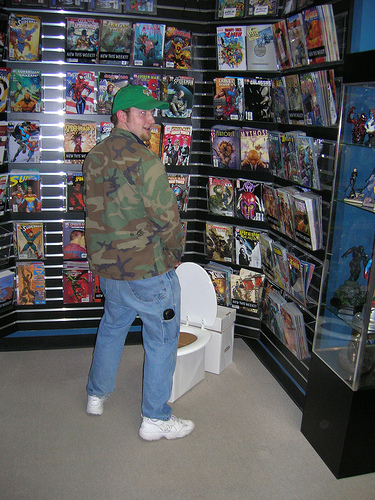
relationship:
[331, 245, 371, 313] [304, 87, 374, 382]
figurine behind glass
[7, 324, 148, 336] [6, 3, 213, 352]
line on wall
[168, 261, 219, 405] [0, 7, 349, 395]
toilet near shelving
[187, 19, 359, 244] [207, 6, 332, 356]
comic books on shelves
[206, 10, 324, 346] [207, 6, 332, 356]
magazines on shelves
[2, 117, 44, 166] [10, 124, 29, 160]
comic featuring batman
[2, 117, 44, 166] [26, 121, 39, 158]
comic featuring superman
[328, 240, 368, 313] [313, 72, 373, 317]
figurine inside glass case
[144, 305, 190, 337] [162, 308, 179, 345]
case inside case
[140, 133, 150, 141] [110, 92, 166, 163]
beard on man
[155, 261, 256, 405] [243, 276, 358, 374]
toilet in corner of rack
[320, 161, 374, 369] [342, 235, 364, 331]
showcase has figurines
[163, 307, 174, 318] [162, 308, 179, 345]
cellphone in case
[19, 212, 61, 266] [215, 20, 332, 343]
comic book hanging on wall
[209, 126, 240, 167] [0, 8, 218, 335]
comic book hanging on wall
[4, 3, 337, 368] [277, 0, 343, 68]
racks of comic books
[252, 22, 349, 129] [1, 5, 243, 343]
books on wall